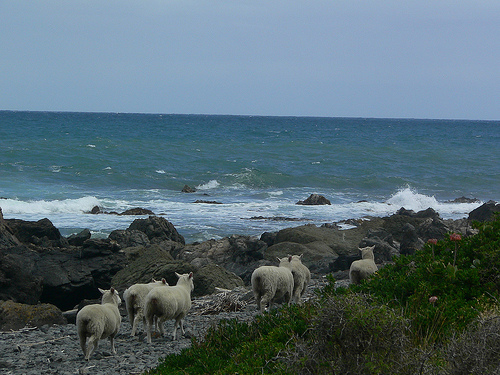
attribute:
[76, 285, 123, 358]
sheep — walking, white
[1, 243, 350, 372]
trail — gray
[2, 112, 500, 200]
water — calm, large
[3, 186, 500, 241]
shore — rocky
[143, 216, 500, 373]
grass — growing, gree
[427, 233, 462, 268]
flowers — small, red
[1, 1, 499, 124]
sky — cloudless, hazy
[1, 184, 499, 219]
waves — white, broken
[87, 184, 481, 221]
rocks — large, gray, wet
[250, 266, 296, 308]
sheep — walking, white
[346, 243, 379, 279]
sheep — walking, white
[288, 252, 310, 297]
sheep — walking, white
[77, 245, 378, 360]
sheeps — walkig